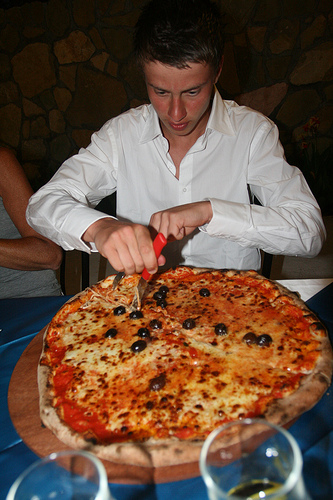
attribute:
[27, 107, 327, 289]
shirt — white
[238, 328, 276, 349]
olives — black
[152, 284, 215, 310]
olives — black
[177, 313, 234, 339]
olives — black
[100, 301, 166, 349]
olives — black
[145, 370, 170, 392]
olives — black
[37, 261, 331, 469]
pizza — cooked, thick, large, cheese, olive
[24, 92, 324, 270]
shirt — long sleeved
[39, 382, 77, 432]
crust — brown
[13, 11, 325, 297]
man — young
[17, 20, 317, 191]
wall — stone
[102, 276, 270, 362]
olives — black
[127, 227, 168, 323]
knife — red, plastic, metal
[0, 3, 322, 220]
wall — brown, stone covered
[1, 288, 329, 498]
tablecloth — blue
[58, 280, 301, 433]
cheese — melted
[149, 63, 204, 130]
face — flushed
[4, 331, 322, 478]
board — wooden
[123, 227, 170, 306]
knife — red